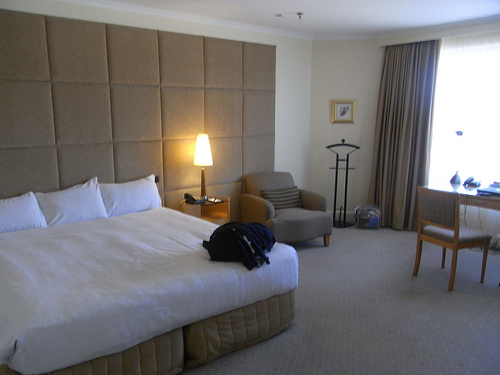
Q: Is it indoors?
A: Yes, it is indoors.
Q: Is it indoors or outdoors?
A: It is indoors.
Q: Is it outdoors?
A: No, it is indoors.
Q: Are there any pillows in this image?
A: Yes, there is a pillow.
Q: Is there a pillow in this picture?
A: Yes, there is a pillow.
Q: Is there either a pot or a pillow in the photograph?
A: Yes, there is a pillow.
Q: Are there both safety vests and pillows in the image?
A: No, there is a pillow but no safety jackets.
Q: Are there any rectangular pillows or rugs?
A: Yes, there is a rectangular pillow.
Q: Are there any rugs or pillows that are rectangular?
A: Yes, the pillow is rectangular.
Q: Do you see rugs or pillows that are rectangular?
A: Yes, the pillow is rectangular.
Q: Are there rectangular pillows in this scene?
A: Yes, there is a rectangular pillow.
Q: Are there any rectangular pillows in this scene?
A: Yes, there is a rectangular pillow.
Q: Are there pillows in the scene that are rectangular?
A: Yes, there is a pillow that is rectangular.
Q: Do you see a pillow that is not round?
A: Yes, there is a rectangular pillow.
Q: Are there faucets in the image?
A: No, there are no faucets.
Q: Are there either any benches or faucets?
A: No, there are no faucets or benches.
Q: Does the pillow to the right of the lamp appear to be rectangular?
A: Yes, the pillow is rectangular.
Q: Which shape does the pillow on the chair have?
A: The pillow has rectangular shape.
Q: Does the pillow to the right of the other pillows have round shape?
A: No, the pillow is rectangular.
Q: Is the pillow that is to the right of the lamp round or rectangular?
A: The pillow is rectangular.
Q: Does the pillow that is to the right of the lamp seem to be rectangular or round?
A: The pillow is rectangular.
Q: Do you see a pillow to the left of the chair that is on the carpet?
A: Yes, there is a pillow to the left of the chair.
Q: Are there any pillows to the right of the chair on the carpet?
A: No, the pillow is to the left of the chair.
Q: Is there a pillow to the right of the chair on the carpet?
A: No, the pillow is to the left of the chair.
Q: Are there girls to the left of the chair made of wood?
A: No, there is a pillow to the left of the chair.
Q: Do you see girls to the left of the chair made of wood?
A: No, there is a pillow to the left of the chair.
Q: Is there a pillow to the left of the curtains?
A: Yes, there is a pillow to the left of the curtains.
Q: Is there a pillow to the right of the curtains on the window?
A: No, the pillow is to the left of the curtains.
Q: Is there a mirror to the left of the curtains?
A: No, there is a pillow to the left of the curtains.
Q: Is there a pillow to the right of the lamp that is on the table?
A: Yes, there is a pillow to the right of the lamp.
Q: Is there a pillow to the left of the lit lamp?
A: No, the pillow is to the right of the lamp.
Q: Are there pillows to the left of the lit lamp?
A: No, the pillow is to the right of the lamp.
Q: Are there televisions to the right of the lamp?
A: No, there is a pillow to the right of the lamp.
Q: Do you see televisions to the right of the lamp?
A: No, there is a pillow to the right of the lamp.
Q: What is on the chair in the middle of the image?
A: The pillow is on the chair.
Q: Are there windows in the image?
A: Yes, there is a window.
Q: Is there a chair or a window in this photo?
A: Yes, there is a window.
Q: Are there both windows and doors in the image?
A: No, there is a window but no doors.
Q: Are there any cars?
A: No, there are no cars.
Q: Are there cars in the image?
A: No, there are no cars.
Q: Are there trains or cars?
A: No, there are no cars or trains.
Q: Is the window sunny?
A: Yes, the window is sunny.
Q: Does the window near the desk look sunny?
A: Yes, the window is sunny.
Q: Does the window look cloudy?
A: No, the window is sunny.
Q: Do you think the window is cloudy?
A: No, the window is sunny.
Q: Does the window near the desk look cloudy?
A: No, the window is sunny.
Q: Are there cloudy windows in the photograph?
A: No, there is a window but it is sunny.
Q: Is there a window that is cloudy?
A: No, there is a window but it is sunny.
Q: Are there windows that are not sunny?
A: No, there is a window but it is sunny.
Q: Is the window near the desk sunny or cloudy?
A: The window is sunny.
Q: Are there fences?
A: No, there are no fences.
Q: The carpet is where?
A: The carpet is on the ground.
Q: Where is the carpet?
A: The carpet is on the ground.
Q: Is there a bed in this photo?
A: Yes, there is a bed.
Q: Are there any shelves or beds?
A: Yes, there is a bed.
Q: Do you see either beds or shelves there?
A: Yes, there is a bed.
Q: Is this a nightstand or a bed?
A: This is a bed.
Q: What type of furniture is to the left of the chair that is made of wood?
A: The piece of furniture is a bed.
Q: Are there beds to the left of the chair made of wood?
A: Yes, there is a bed to the left of the chair.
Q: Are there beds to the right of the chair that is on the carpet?
A: No, the bed is to the left of the chair.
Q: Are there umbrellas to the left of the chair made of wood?
A: No, there is a bed to the left of the chair.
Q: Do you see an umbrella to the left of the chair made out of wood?
A: No, there is a bed to the left of the chair.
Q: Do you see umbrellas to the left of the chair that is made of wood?
A: No, there is a bed to the left of the chair.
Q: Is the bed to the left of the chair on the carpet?
A: Yes, the bed is to the left of the chair.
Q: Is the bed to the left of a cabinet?
A: No, the bed is to the left of the chair.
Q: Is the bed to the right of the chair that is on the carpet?
A: No, the bed is to the left of the chair.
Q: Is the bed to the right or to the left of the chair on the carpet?
A: The bed is to the left of the chair.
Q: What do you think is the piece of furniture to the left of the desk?
A: The piece of furniture is a bed.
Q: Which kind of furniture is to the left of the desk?
A: The piece of furniture is a bed.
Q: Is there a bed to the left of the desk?
A: Yes, there is a bed to the left of the desk.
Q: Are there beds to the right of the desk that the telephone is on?
A: No, the bed is to the left of the desk.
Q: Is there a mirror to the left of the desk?
A: No, there is a bed to the left of the desk.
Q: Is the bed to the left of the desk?
A: Yes, the bed is to the left of the desk.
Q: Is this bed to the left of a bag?
A: No, the bed is to the left of the desk.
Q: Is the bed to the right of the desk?
A: No, the bed is to the left of the desk.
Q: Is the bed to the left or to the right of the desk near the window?
A: The bed is to the left of the desk.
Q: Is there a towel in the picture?
A: No, there are no towels.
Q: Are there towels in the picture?
A: No, there are no towels.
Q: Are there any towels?
A: No, there are no towels.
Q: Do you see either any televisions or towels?
A: No, there are no towels or televisions.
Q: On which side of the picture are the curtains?
A: The curtains are on the right of the image.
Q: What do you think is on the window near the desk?
A: The curtains are on the window.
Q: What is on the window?
A: The curtains are on the window.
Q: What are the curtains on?
A: The curtains are on the window.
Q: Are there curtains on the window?
A: Yes, there are curtains on the window.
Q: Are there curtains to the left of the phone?
A: Yes, there are curtains to the left of the phone.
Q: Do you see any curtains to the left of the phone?
A: Yes, there are curtains to the left of the phone.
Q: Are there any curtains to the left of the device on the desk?
A: Yes, there are curtains to the left of the phone.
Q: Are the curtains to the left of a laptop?
A: No, the curtains are to the left of the phone.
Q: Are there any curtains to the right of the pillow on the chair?
A: Yes, there are curtains to the right of the pillow.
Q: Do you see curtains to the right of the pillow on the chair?
A: Yes, there are curtains to the right of the pillow.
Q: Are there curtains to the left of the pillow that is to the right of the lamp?
A: No, the curtains are to the right of the pillow.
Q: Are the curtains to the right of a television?
A: No, the curtains are to the right of the pillow.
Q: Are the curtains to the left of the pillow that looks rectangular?
A: No, the curtains are to the right of the pillow.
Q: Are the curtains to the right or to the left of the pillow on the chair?
A: The curtains are to the right of the pillow.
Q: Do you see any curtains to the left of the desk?
A: Yes, there are curtains to the left of the desk.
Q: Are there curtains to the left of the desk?
A: Yes, there are curtains to the left of the desk.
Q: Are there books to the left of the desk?
A: No, there are curtains to the left of the desk.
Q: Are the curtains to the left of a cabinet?
A: No, the curtains are to the left of the desk.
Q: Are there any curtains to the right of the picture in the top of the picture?
A: Yes, there are curtains to the right of the picture.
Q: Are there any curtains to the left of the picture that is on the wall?
A: No, the curtains are to the right of the picture.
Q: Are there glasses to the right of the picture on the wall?
A: No, there are curtains to the right of the picture.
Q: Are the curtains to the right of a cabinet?
A: No, the curtains are to the right of the picture.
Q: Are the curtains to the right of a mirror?
A: No, the curtains are to the right of the chair.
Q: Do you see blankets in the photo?
A: Yes, there is a blanket.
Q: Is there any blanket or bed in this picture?
A: Yes, there is a blanket.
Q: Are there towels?
A: No, there are no towels.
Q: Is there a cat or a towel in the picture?
A: No, there are no towels or cats.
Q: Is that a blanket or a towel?
A: That is a blanket.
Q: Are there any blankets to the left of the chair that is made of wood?
A: Yes, there is a blanket to the left of the chair.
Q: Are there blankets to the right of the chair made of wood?
A: No, the blanket is to the left of the chair.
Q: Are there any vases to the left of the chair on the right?
A: No, there is a blanket to the left of the chair.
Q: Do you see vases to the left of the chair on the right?
A: No, there is a blanket to the left of the chair.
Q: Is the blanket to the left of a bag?
A: No, the blanket is to the left of the chair.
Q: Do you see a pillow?
A: Yes, there is a pillow.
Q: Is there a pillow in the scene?
A: Yes, there is a pillow.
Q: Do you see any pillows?
A: Yes, there is a pillow.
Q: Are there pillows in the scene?
A: Yes, there is a pillow.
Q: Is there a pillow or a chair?
A: Yes, there is a pillow.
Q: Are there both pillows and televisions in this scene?
A: No, there is a pillow but no televisions.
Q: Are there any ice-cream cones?
A: No, there are no ice-cream cones.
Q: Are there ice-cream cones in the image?
A: No, there are no ice-cream cones.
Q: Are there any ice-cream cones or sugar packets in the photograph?
A: No, there are no ice-cream cones or sugar packets.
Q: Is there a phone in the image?
A: Yes, there is a phone.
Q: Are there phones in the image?
A: Yes, there is a phone.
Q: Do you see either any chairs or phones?
A: Yes, there is a phone.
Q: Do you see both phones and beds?
A: Yes, there are both a phone and a bed.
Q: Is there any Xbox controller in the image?
A: No, there are no Xbox controllers.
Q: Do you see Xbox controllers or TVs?
A: No, there are no Xbox controllers or tvs.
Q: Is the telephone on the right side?
A: Yes, the telephone is on the right of the image.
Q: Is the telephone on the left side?
A: No, the telephone is on the right of the image.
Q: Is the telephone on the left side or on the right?
A: The telephone is on the right of the image.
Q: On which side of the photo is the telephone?
A: The telephone is on the right of the image.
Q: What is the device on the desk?
A: The device is a phone.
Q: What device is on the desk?
A: The device is a phone.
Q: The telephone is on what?
A: The telephone is on the desk.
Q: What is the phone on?
A: The telephone is on the desk.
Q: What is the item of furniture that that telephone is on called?
A: The piece of furniture is a desk.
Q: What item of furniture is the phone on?
A: The telephone is on the desk.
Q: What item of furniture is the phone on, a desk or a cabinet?
A: The phone is on a desk.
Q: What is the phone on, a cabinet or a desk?
A: The phone is on a desk.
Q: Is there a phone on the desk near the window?
A: Yes, there is a phone on the desk.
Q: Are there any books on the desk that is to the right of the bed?
A: No, there is a phone on the desk.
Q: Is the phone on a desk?
A: Yes, the phone is on a desk.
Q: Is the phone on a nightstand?
A: No, the phone is on a desk.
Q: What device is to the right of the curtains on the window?
A: The device is a phone.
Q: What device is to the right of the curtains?
A: The device is a phone.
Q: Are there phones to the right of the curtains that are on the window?
A: Yes, there is a phone to the right of the curtains.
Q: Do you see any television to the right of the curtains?
A: No, there is a phone to the right of the curtains.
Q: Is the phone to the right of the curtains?
A: Yes, the phone is to the right of the curtains.